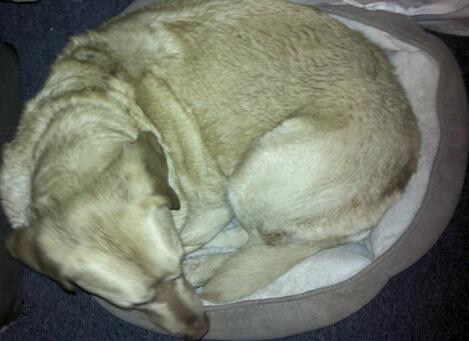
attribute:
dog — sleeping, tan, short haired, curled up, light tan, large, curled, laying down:
[0, 1, 423, 340]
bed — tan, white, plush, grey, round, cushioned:
[78, 0, 468, 340]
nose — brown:
[175, 312, 216, 340]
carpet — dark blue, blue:
[1, 1, 131, 133]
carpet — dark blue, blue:
[0, 254, 467, 337]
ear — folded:
[121, 129, 186, 218]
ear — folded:
[5, 219, 82, 299]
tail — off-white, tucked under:
[200, 227, 374, 306]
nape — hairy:
[24, 91, 119, 133]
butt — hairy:
[337, 100, 427, 254]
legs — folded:
[146, 107, 399, 309]